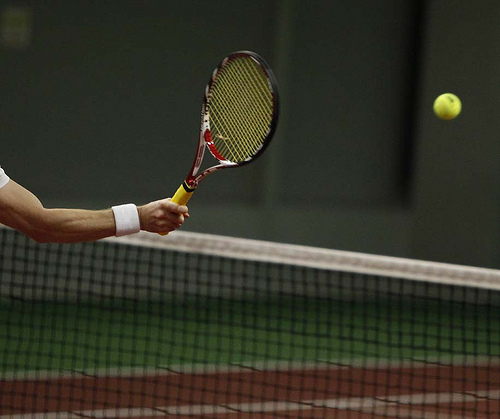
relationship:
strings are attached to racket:
[224, 85, 255, 134] [164, 50, 286, 208]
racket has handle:
[171, 48, 282, 203] [172, 179, 194, 205]